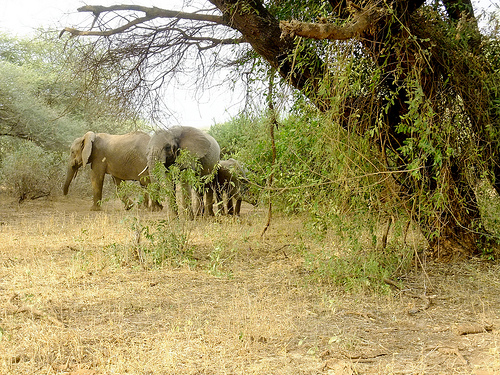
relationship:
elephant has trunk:
[140, 118, 221, 214] [151, 169, 158, 211]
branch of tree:
[220, 3, 389, 135] [70, 1, 499, 250]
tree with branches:
[70, 1, 499, 250] [76, 1, 373, 121]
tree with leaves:
[70, 1, 499, 250] [286, 27, 477, 196]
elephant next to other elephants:
[200, 165, 262, 209] [63, 129, 214, 208]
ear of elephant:
[81, 133, 98, 168] [64, 131, 151, 209]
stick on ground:
[111, 208, 233, 267] [2, 192, 485, 370]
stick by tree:
[111, 208, 233, 267] [70, 1, 499, 250]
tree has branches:
[70, 1, 499, 250] [76, 1, 373, 121]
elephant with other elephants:
[200, 165, 262, 209] [63, 129, 214, 208]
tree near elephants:
[70, 1, 499, 250] [59, 118, 243, 199]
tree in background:
[2, 34, 125, 202] [1, 3, 494, 181]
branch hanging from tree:
[220, 3, 389, 135] [70, 1, 499, 250]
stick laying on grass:
[111, 208, 233, 267] [6, 203, 499, 370]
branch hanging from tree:
[275, 8, 363, 41] [70, 1, 499, 250]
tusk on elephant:
[135, 165, 148, 178] [140, 118, 221, 214]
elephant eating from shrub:
[140, 118, 221, 214] [114, 151, 199, 219]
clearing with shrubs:
[2, 192, 485, 370] [2, 109, 400, 287]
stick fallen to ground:
[111, 208, 233, 267] [2, 192, 485, 370]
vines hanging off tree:
[266, 20, 466, 289] [70, 1, 499, 250]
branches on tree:
[76, 1, 373, 121] [70, 1, 499, 250]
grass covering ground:
[6, 203, 499, 370] [2, 192, 485, 370]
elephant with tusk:
[140, 118, 221, 214] [135, 165, 148, 178]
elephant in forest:
[200, 165, 262, 209] [4, 1, 495, 374]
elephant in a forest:
[140, 118, 221, 214] [4, 1, 495, 374]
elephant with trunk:
[140, 118, 221, 214] [151, 169, 158, 211]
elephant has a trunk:
[200, 165, 262, 209] [205, 187, 218, 216]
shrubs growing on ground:
[2, 109, 400, 287] [2, 192, 485, 370]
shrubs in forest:
[2, 109, 400, 287] [4, 1, 495, 374]